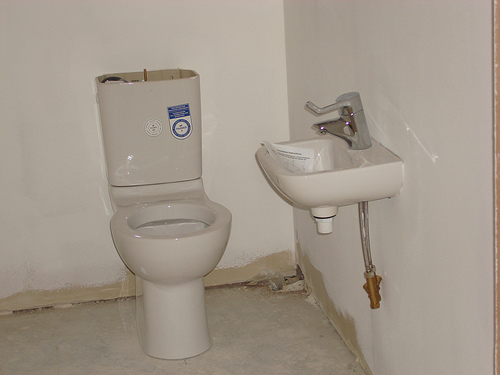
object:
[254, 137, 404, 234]
sink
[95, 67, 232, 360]
toilet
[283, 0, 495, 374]
wall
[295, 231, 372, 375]
crack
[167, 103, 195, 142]
sticker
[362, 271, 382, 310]
copper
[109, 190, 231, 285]
toilet bowl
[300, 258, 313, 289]
scrape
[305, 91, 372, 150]
faucet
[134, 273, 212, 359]
base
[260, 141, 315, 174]
paper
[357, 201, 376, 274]
pipe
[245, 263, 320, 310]
corner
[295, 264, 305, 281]
crack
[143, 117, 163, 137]
label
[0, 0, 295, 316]
wall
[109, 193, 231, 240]
lid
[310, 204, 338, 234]
bottom drain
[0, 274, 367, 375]
ground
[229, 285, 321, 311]
water damage